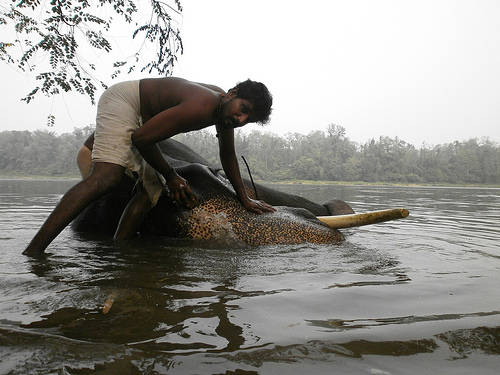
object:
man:
[22, 79, 275, 257]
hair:
[226, 79, 274, 127]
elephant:
[68, 137, 417, 247]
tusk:
[315, 207, 410, 231]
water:
[0, 178, 497, 374]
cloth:
[91, 78, 166, 209]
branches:
[131, 0, 159, 59]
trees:
[449, 146, 484, 173]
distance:
[0, 124, 499, 191]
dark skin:
[20, 75, 278, 263]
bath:
[174, 187, 203, 211]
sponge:
[178, 189, 200, 210]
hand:
[166, 174, 196, 208]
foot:
[328, 206, 357, 217]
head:
[164, 182, 410, 246]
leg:
[187, 148, 330, 217]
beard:
[219, 101, 240, 130]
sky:
[0, 0, 497, 146]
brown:
[1, 180, 499, 374]